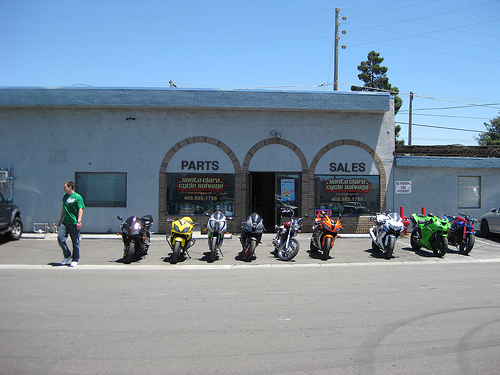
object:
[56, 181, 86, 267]
brownhair man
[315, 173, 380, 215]
window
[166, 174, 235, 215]
window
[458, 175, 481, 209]
blinds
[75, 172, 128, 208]
blinds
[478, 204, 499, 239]
automobile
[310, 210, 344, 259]
bike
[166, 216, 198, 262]
bike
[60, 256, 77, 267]
shoes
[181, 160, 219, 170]
sign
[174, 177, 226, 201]
sign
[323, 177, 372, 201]
sign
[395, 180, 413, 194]
sign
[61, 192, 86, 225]
green shirt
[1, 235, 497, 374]
street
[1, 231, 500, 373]
store`s front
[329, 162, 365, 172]
sales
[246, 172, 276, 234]
open door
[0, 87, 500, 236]
auto store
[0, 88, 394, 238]
store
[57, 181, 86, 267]
man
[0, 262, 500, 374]
road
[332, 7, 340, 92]
pole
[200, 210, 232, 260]
motorcycle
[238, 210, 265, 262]
motorcycle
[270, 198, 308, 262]
motorcycle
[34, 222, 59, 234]
pipe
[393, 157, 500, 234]
building wall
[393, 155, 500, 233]
wall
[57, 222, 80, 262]
jeans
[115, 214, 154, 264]
motorcycle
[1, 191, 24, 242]
car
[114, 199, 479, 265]
motorcycles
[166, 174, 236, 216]
front window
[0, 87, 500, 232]
motorcycle shop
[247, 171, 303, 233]
door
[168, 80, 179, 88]
object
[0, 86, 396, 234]
building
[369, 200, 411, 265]
motorcycle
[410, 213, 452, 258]
bike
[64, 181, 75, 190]
hair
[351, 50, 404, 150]
tree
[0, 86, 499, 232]
building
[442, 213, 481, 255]
motorcycle